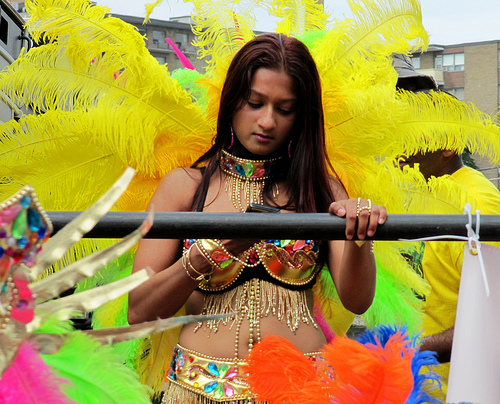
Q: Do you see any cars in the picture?
A: No, there are no cars.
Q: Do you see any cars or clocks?
A: No, there are no cars or clocks.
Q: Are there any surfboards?
A: No, there are no surfboards.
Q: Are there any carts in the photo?
A: No, there are no carts.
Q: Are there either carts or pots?
A: No, there are no carts or pots.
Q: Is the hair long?
A: Yes, the hair is long.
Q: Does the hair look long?
A: Yes, the hair is long.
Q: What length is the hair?
A: The hair is long.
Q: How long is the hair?
A: The hair is long.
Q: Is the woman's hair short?
A: No, the hair is long.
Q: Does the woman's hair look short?
A: No, the hair is long.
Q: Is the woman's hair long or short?
A: The hair is long.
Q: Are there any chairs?
A: No, there are no chairs.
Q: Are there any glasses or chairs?
A: No, there are no chairs or glasses.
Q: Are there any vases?
A: No, there are no vases.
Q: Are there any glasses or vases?
A: No, there are no vases or glasses.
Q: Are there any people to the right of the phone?
A: Yes, there is a person to the right of the phone.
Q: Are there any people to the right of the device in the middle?
A: Yes, there is a person to the right of the phone.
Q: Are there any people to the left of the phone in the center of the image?
A: No, the person is to the right of the phone.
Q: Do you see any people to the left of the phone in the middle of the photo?
A: No, the person is to the right of the phone.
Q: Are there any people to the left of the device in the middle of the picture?
A: No, the person is to the right of the phone.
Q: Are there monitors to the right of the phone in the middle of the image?
A: No, there is a person to the right of the telephone.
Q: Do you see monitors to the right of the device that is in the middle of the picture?
A: No, there is a person to the right of the telephone.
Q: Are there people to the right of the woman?
A: Yes, there is a person to the right of the woman.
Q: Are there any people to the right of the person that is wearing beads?
A: Yes, there is a person to the right of the woman.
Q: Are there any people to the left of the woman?
A: No, the person is to the right of the woman.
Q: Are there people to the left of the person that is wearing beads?
A: No, the person is to the right of the woman.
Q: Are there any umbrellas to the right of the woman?
A: No, there is a person to the right of the woman.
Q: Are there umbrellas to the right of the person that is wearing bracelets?
A: No, there is a person to the right of the woman.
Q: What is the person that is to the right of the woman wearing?
A: The person is wearing a shirt.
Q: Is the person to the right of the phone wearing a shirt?
A: Yes, the person is wearing a shirt.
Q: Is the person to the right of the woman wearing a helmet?
A: No, the person is wearing a shirt.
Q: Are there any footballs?
A: No, there are no footballs.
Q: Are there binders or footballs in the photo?
A: No, there are no footballs or binders.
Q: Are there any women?
A: Yes, there is a woman.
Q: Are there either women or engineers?
A: Yes, there is a woman.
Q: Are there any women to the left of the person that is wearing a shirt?
A: Yes, there is a woman to the left of the person.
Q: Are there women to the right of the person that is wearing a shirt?
A: No, the woman is to the left of the person.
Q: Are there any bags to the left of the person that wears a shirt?
A: No, there is a woman to the left of the person.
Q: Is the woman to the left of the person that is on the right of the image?
A: Yes, the woman is to the left of the person.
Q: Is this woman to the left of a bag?
A: No, the woman is to the left of the person.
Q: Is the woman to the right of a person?
A: No, the woman is to the left of a person.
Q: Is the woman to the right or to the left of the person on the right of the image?
A: The woman is to the left of the person.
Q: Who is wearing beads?
A: The woman is wearing beads.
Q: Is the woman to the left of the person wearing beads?
A: Yes, the woman is wearing beads.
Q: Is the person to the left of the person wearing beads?
A: Yes, the woman is wearing beads.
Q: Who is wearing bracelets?
A: The woman is wearing bracelets.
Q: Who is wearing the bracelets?
A: The woman is wearing bracelets.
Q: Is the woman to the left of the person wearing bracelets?
A: Yes, the woman is wearing bracelets.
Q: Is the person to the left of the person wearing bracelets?
A: Yes, the woman is wearing bracelets.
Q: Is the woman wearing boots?
A: No, the woman is wearing bracelets.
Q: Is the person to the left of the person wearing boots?
A: No, the woman is wearing bracelets.